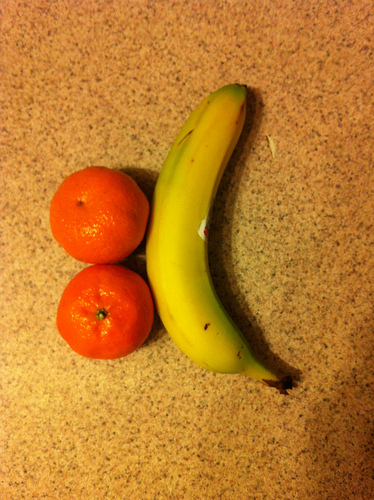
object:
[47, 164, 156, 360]
oranges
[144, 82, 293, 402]
fruit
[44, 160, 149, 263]
fruit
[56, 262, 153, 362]
fruit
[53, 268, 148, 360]
tangerine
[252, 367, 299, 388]
stalk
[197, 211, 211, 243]
sticker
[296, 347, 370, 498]
shadow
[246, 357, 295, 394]
stem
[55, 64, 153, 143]
table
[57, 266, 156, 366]
clementine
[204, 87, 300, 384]
shadow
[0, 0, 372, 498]
floor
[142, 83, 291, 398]
banana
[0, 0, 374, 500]
counter top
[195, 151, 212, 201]
banana peel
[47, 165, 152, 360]
tangerines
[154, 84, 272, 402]
banana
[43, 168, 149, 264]
orange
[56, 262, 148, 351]
orange